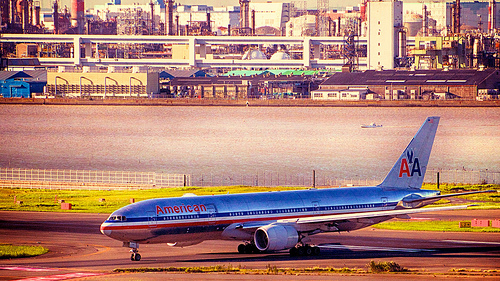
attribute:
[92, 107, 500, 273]
airplane — large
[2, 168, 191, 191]
fence — white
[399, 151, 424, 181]
logo — american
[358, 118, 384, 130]
boat — small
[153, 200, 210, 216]
word — red, painted